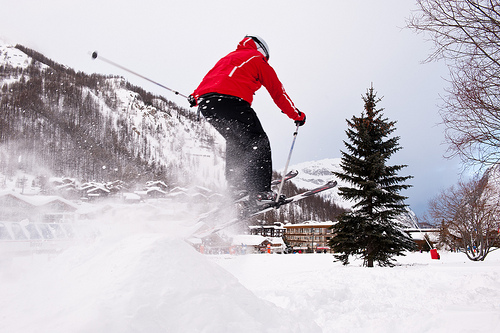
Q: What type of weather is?
A: It is overcast.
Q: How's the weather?
A: It is overcast.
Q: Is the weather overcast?
A: Yes, it is overcast.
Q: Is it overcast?
A: Yes, it is overcast.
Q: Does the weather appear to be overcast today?
A: Yes, it is overcast.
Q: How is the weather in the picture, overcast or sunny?
A: It is overcast.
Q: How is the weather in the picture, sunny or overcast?
A: It is overcast.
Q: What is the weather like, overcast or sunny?
A: It is overcast.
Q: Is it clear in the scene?
A: No, it is overcast.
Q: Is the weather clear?
A: No, it is overcast.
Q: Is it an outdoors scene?
A: Yes, it is outdoors.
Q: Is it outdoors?
A: Yes, it is outdoors.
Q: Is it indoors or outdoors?
A: It is outdoors.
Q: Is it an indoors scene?
A: No, it is outdoors.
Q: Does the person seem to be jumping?
A: Yes, the person is jumping.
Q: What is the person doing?
A: The person is jumping.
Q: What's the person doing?
A: The person is jumping.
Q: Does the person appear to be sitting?
A: No, the person is jumping.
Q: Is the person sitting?
A: No, the person is jumping.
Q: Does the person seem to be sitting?
A: No, the person is jumping.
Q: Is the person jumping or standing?
A: The person is jumping.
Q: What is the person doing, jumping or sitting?
A: The person is jumping.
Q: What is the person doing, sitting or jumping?
A: The person is jumping.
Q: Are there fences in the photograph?
A: No, there are no fences.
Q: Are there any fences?
A: No, there are no fences.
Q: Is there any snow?
A: Yes, there is snow.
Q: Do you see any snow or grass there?
A: Yes, there is snow.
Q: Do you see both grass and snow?
A: No, there is snow but no grass.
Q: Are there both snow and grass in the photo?
A: No, there is snow but no grass.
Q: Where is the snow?
A: The snow is on the mountain.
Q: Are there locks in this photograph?
A: No, there are no locks.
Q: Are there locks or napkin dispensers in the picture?
A: No, there are no locks or napkin dispensers.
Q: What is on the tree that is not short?
A: The trunks are on the tree.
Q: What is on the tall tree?
A: The trunks are on the tree.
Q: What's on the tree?
A: The trunks are on the tree.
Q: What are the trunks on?
A: The trunks are on the tree.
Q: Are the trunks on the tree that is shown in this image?
A: Yes, the trunks are on the tree.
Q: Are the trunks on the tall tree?
A: Yes, the trunks are on the tree.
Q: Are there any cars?
A: No, there are no cars.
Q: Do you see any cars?
A: No, there are no cars.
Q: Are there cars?
A: No, there are no cars.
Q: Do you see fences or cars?
A: No, there are no cars or fences.